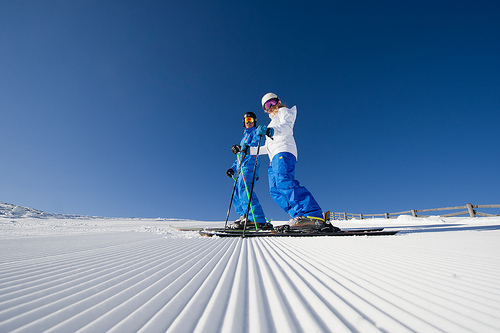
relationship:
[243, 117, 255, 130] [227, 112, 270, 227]
face of person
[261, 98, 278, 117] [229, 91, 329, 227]
face of person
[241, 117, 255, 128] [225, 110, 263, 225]
face of man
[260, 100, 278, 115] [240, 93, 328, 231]
face of man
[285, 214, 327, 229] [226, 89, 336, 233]
shoe of man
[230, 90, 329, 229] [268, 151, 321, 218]
man wearing pants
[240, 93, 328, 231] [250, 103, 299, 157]
man wearing shirt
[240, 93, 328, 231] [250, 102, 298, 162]
man wearing jacket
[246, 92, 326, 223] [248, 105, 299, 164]
man wearing jacket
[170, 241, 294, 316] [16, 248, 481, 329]
snow on ground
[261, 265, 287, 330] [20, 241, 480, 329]
line in snow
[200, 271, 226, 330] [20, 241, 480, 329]
line in snow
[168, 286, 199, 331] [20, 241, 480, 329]
line in snow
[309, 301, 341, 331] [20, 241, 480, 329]
line in snow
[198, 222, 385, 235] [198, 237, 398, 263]
skating machine in ice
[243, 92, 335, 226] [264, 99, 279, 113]
woman wearing goggles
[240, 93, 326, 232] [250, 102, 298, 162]
woman in jacket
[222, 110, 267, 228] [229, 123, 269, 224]
man wearing suit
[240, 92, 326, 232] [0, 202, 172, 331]
person on mountain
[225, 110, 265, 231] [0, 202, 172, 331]
person on mountain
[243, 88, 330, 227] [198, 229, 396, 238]
person on skis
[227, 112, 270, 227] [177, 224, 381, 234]
person on skis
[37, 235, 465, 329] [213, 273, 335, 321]
ground covered in snow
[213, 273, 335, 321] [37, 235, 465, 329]
snow covering ground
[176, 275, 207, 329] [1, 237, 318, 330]
line on ground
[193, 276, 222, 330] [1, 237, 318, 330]
line on ground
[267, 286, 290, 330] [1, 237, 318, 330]
line on ground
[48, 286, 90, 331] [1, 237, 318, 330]
line on ground